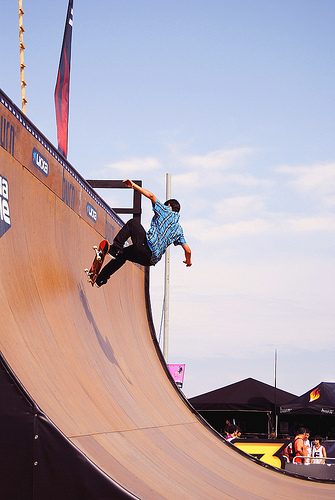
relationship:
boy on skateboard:
[78, 167, 200, 289] [74, 235, 112, 288]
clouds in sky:
[82, 141, 332, 397] [190, 83, 311, 169]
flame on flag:
[54, 49, 68, 155] [53, 1, 75, 158]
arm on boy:
[177, 226, 191, 265] [83, 178, 192, 289]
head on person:
[165, 197, 181, 212] [93, 177, 192, 288]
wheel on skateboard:
[93, 245, 97, 250] [85, 238, 107, 285]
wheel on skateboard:
[86, 278, 91, 283] [85, 238, 107, 285]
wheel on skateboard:
[86, 277, 91, 283] [84, 239, 108, 284]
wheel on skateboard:
[83, 267, 89, 274] [84, 239, 108, 284]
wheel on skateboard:
[97, 255, 101, 261] [84, 239, 108, 284]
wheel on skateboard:
[93, 245, 97, 250] [84, 239, 108, 284]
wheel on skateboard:
[76, 241, 106, 253] [84, 239, 108, 284]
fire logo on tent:
[308, 387, 320, 402] [184, 370, 333, 443]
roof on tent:
[188, 375, 299, 408] [183, 376, 333, 436]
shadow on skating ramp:
[72, 279, 136, 387] [0, 87, 334, 498]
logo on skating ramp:
[83, 200, 101, 223] [0, 87, 334, 498]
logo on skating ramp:
[30, 145, 50, 178] [0, 87, 334, 498]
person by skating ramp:
[288, 428, 306, 463] [0, 87, 334, 498]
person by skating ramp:
[313, 436, 327, 465] [0, 87, 334, 498]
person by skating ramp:
[304, 431, 311, 464] [0, 87, 334, 498]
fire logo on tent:
[33, 151, 97, 220] [279, 381, 333, 438]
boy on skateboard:
[83, 178, 192, 289] [86, 239, 118, 283]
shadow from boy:
[77, 281, 133, 385] [83, 178, 192, 289]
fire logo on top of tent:
[308, 387, 320, 402] [279, 381, 333, 438]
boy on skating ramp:
[83, 178, 192, 289] [0, 87, 334, 498]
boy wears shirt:
[83, 178, 192, 289] [145, 194, 186, 258]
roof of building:
[188, 375, 302, 408] [183, 376, 331, 443]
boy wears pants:
[83, 178, 192, 289] [98, 218, 151, 282]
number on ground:
[230, 436, 293, 470] [197, 415, 321, 498]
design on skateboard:
[73, 228, 123, 292] [82, 239, 110, 286]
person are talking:
[293, 427, 309, 465] [282, 425, 324, 462]